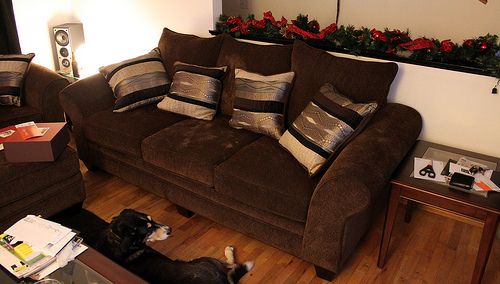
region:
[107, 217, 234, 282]
A black and brown dog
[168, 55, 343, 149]
pillows on the couch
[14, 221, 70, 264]
Books on the table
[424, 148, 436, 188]
Scissors on the table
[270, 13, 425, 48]
Flowers in the background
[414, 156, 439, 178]
Scissors on wooden end table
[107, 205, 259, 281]
Dog laying on hardwood floor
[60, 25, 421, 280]
Brown couch in living room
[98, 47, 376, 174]
Pillows on brown couch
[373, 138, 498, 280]
Wooden end table in living room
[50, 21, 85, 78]
Stereo speaker in corner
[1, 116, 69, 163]
Cardboard box on chair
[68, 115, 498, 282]
Hardwood floor in living room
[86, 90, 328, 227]
Brown cushions on couch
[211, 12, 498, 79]
Plant box behind sofa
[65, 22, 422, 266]
the couch is brown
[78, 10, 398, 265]
the couch is brown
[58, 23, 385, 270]
the couch is brown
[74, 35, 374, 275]
the couch is brown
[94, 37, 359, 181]
pillows on the couch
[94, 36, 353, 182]
pillows on the couch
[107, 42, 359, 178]
pillows on the couch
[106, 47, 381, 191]
pillows on the couch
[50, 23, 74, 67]
The speakers in the corner.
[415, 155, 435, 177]
The scissors on the table.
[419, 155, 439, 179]
The handle of the scissors.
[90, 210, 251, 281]
The dog sitting on the floor.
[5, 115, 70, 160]
The box on the sofa.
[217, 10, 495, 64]
The flowers on the mantle.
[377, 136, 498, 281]
The wooden side table.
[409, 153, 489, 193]
The white papers on the side table.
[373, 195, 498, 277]
The legs of the side table.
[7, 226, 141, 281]
The table behind the dog.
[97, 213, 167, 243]
head of the dog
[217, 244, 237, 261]
paw of the dog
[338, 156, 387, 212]
arm of the couch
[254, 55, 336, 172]
cushion on the couch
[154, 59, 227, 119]
black and silver throw pillow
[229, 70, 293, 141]
black and silver throw pillow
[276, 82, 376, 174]
black and silver throw pillow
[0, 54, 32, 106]
black and silver throw pillow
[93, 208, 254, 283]
a black and brown dog with white feet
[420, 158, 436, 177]
scissors with black handles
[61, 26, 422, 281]
brown plush sofa with pillows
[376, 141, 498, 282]
wooden end table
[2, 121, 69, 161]
cardboard box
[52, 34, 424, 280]
A dark brown sofa.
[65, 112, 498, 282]
Hardwood floors.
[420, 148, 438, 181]
A black handled pair of scissors.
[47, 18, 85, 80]
A black and silver speaker.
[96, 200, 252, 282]
A black dog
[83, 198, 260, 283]
A dog laying on the ground.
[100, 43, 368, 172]
Accent pillows on a sofa.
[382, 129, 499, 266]
An end table.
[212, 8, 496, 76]
Green and red garland.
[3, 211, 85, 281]
A stack of papers and books.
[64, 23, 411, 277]
the couch is brown in color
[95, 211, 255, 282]
the dog is laying on the floor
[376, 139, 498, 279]
a sidetable is besides the sofa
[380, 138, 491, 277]
the table is made of wood